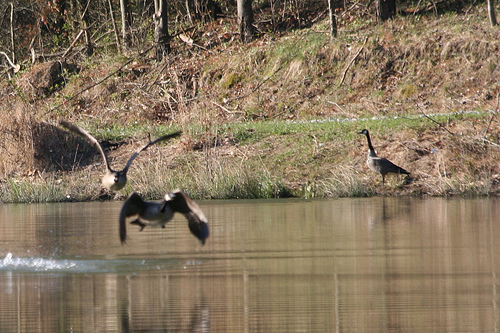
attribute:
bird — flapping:
[117, 187, 212, 250]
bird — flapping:
[59, 120, 181, 191]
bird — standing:
[331, 121, 437, 196]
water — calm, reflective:
[2, 198, 483, 331]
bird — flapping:
[359, 124, 413, 180]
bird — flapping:
[60, 115, 185, 194]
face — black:
[354, 125, 370, 138]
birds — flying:
[53, 114, 230, 265]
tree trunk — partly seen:
[146, 20, 165, 58]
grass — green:
[88, 109, 498, 144]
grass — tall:
[4, 112, 498, 197]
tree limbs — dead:
[252, 32, 381, 112]